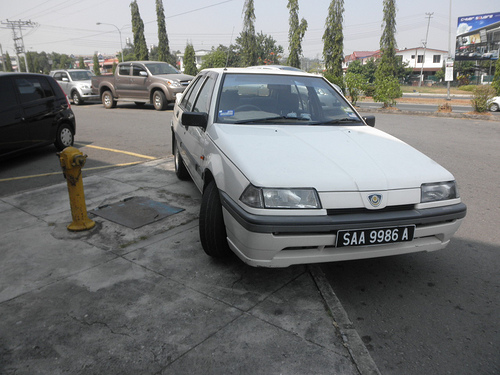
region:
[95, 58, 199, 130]
a truck parked on the side of a road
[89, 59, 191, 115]
a truck on the side of a street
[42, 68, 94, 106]
a car parked on the street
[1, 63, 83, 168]
a car parked on the side of the street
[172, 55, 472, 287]
a car parked on the sidewalk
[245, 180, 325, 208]
the headlight of a car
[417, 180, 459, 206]
the headlight of a car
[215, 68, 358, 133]
the windshield of a car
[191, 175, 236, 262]
the front wheel of a car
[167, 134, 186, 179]
the rear wheel of a car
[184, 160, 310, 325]
the car is parked on the sidewalk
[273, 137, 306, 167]
the car is white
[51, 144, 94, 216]
the hydrant is yellow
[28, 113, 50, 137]
the car is black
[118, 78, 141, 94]
the truck is gray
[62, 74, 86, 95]
the car is silver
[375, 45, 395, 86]
the trees are green inn color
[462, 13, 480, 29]
the sign is blue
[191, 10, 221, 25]
the sky is hazy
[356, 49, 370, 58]
the roof is red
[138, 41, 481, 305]
a white car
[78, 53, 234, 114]
a gray truck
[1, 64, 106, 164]
a black vehicle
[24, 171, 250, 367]
a cement sidewalk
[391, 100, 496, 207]
a black tared road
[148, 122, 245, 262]
black tires on a white car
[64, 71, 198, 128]
black tires on a gray truck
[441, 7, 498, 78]
a billboard on the side of the road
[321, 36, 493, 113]
a white house next to a road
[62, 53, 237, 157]
a gray truck driving on the road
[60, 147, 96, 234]
a yellow fire hydrant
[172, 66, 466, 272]
white car parked on curb by a fire hydrant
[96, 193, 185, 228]
metal late by the fire hydrant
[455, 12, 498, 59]
large billboard across the street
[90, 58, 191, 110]
light brown pick-up truck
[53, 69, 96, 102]
silver vehicle behind the pick-up truck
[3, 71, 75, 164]
black hatchback by the fire hydrant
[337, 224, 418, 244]
the white car's license plate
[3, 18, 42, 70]
large power pole on the left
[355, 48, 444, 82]
white house by the billboard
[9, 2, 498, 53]
pale blue daytime sky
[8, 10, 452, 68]
wires suspended from poles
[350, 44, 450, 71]
red roof on building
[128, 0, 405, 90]
line of tall trees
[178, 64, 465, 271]
front of white car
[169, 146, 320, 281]
two tires on sidewalk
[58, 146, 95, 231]
yellow hydrant on sidewalk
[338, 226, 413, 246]
black license plate with white numbers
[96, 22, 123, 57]
light on curved pole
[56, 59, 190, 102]
two cars on street